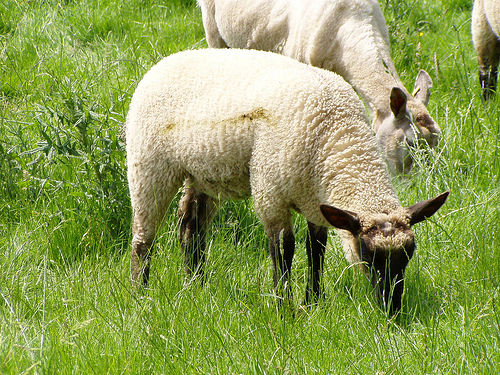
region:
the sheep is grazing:
[97, 27, 468, 355]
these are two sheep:
[105, 5, 462, 320]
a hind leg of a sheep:
[455, 0, 495, 110]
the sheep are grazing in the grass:
[90, 6, 436, 326]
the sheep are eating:
[75, 6, 485, 351]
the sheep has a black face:
[327, 178, 471, 328]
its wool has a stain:
[142, 93, 282, 145]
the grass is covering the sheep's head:
[377, 60, 467, 219]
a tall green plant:
[17, 35, 128, 249]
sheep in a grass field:
[85, 32, 473, 342]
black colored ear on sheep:
[315, 199, 361, 232]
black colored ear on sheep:
[407, 189, 451, 228]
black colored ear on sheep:
[385, 85, 408, 117]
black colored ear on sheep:
[412, 65, 433, 105]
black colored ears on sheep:
[322, 190, 450, 237]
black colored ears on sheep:
[390, 68, 433, 115]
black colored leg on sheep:
[129, 239, 152, 287]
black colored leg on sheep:
[268, 226, 298, 319]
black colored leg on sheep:
[305, 223, 328, 311]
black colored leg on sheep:
[177, 206, 211, 272]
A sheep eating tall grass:
[104, 42, 452, 334]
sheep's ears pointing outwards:
[302, 172, 450, 245]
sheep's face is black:
[358, 239, 429, 327]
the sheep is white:
[124, 50, 450, 330]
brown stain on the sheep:
[225, 102, 290, 129]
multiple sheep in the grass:
[82, 2, 498, 349]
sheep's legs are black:
[110, 198, 342, 319]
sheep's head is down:
[302, 164, 450, 318]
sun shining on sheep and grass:
[1, 2, 496, 371]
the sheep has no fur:
[196, 0, 427, 167]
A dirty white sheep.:
[125, 47, 450, 321]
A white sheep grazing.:
[199, 0, 444, 177]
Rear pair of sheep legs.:
[471, 0, 498, 100]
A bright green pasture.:
[1, 0, 499, 373]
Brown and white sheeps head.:
[318, 189, 455, 318]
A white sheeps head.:
[373, 70, 443, 176]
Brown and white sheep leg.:
[126, 151, 174, 298]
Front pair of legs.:
[254, 193, 326, 320]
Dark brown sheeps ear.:
[403, 188, 453, 223]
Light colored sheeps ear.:
[412, 67, 433, 105]